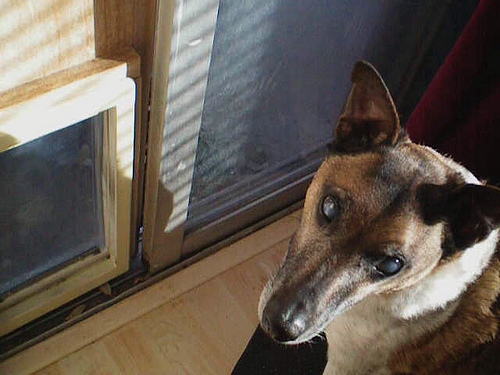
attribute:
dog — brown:
[252, 279, 329, 349]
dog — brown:
[221, 54, 497, 374]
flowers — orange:
[1, 143, 105, 253]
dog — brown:
[256, 60, 498, 372]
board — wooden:
[46, 58, 178, 293]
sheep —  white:
[129, 207, 225, 266]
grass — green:
[192, 158, 204, 173]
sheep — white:
[121, 278, 200, 361]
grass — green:
[134, 304, 219, 375]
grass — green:
[121, 346, 172, 375]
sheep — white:
[130, 313, 217, 375]